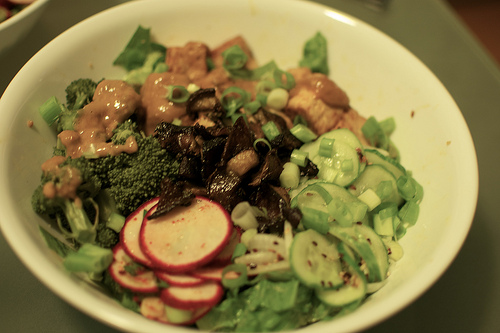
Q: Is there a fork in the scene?
A: No, there are no forks.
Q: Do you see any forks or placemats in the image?
A: No, there are no forks or placemats.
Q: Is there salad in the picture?
A: Yes, there is salad.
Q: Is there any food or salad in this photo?
A: Yes, there is salad.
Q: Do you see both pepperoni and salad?
A: No, there is salad but no pepperoni.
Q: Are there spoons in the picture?
A: No, there are no spoons.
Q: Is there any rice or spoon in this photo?
A: No, there are no spoons or rice.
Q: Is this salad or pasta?
A: This is salad.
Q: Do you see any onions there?
A: Yes, there is an onion.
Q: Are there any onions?
A: Yes, there is an onion.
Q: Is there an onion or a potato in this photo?
A: Yes, there is an onion.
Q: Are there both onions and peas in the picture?
A: No, there is an onion but no peas.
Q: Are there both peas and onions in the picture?
A: No, there is an onion but no peas.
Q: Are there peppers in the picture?
A: No, there are no peppers.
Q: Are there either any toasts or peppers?
A: No, there are no peppers or toasts.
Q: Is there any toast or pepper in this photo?
A: No, there are no peppers or toasts.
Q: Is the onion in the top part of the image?
A: Yes, the onion is in the top of the image.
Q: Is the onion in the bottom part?
A: No, the onion is in the top of the image.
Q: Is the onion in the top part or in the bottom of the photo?
A: The onion is in the top of the image.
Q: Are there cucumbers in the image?
A: Yes, there is a cucumber.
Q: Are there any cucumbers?
A: Yes, there is a cucumber.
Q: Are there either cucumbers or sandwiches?
A: Yes, there is a cucumber.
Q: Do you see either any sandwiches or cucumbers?
A: Yes, there is a cucumber.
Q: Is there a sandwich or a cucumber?
A: Yes, there is a cucumber.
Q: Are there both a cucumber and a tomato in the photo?
A: No, there is a cucumber but no tomatoes.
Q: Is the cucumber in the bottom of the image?
A: Yes, the cucumber is in the bottom of the image.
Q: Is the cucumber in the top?
A: No, the cucumber is in the bottom of the image.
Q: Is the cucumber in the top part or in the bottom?
A: The cucumber is in the bottom of the image.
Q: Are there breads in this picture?
A: No, there are no breads.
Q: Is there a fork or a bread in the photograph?
A: No, there are no breads or forks.